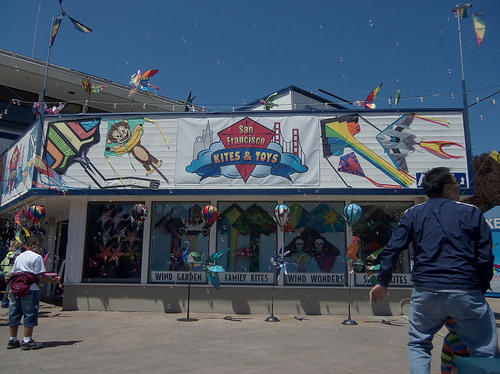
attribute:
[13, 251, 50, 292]
shirt — white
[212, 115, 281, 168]
san francisco kites — name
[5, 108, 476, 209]
sign — colorful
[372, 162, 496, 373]
man — looking upward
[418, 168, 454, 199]
hair — dark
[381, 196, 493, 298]
jacket — blue, wrinkled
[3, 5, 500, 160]
sky — blue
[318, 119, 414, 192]
kite — rainbow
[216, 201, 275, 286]
sign — white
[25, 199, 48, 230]
balls — hanging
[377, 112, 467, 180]
kite — painted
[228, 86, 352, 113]
building — white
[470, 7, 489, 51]
flag — rainbow